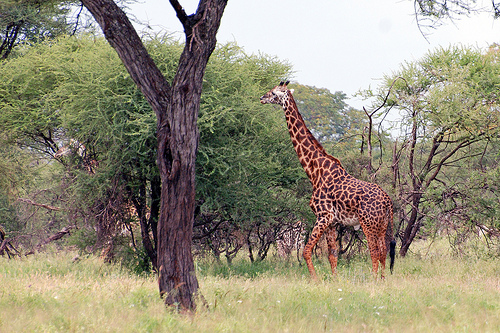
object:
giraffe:
[257, 80, 398, 284]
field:
[1, 236, 500, 333]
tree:
[376, 42, 500, 258]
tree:
[80, 4, 238, 315]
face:
[260, 86, 281, 104]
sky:
[2, 1, 499, 147]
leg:
[302, 213, 334, 279]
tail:
[388, 197, 396, 275]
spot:
[306, 158, 318, 173]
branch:
[407, 0, 437, 46]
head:
[260, 77, 297, 106]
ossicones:
[284, 80, 292, 85]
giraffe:
[53, 137, 155, 273]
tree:
[119, 32, 210, 317]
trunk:
[394, 104, 452, 261]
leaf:
[206, 119, 215, 131]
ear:
[277, 81, 284, 87]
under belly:
[333, 216, 360, 227]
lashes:
[270, 90, 277, 95]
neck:
[283, 101, 338, 182]